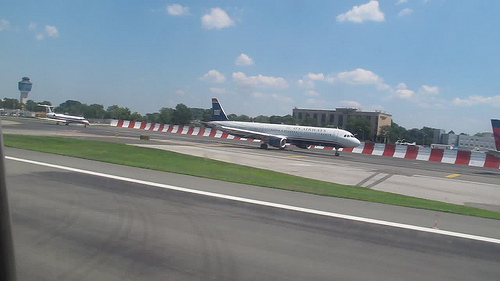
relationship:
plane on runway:
[198, 94, 363, 161] [0, 107, 499, 217]